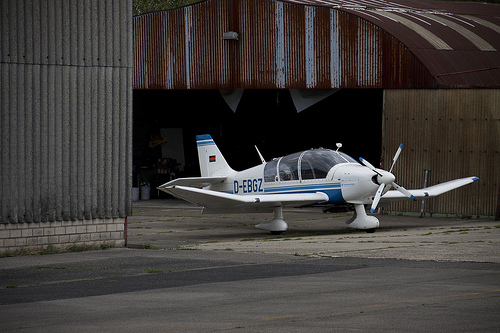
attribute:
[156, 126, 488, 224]
plane — small, blue, white, parked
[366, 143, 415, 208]
propeller — bladed, blue, white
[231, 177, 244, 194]
d — blue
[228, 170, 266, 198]
d-e8gz — blue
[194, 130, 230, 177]
tail — white, blue, red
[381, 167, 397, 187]
nose — white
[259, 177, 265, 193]
z — blue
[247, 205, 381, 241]
landing gear — white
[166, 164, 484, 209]
wings — blue, white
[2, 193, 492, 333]
concrete — dark grey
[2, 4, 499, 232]
hangar — sheet  metal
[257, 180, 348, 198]
stripe — blue